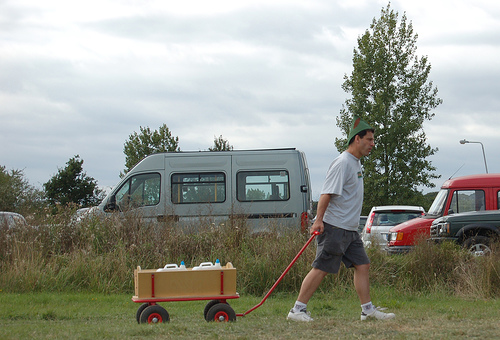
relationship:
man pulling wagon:
[286, 120, 382, 313] [125, 262, 289, 321]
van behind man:
[73, 153, 345, 243] [286, 120, 382, 313]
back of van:
[257, 144, 320, 252] [73, 153, 345, 243]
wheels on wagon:
[132, 304, 241, 337] [125, 262, 289, 321]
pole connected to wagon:
[237, 236, 319, 284] [125, 262, 289, 321]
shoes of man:
[297, 301, 407, 333] [286, 120, 382, 313]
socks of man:
[295, 285, 381, 311] [286, 120, 382, 313]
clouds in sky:
[253, 33, 318, 74] [55, 26, 151, 91]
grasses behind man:
[38, 229, 112, 290] [286, 120, 382, 313]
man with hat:
[286, 120, 382, 313] [344, 118, 376, 133]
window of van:
[234, 169, 308, 204] [73, 153, 345, 243]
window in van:
[234, 169, 308, 204] [73, 153, 345, 243]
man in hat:
[286, 120, 382, 313] [344, 118, 376, 133]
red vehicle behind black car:
[391, 184, 500, 258] [437, 218, 497, 263]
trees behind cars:
[6, 158, 137, 211] [391, 184, 500, 258]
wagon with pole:
[125, 262, 289, 321] [237, 236, 319, 284]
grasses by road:
[38, 229, 112, 290] [76, 318, 120, 338]